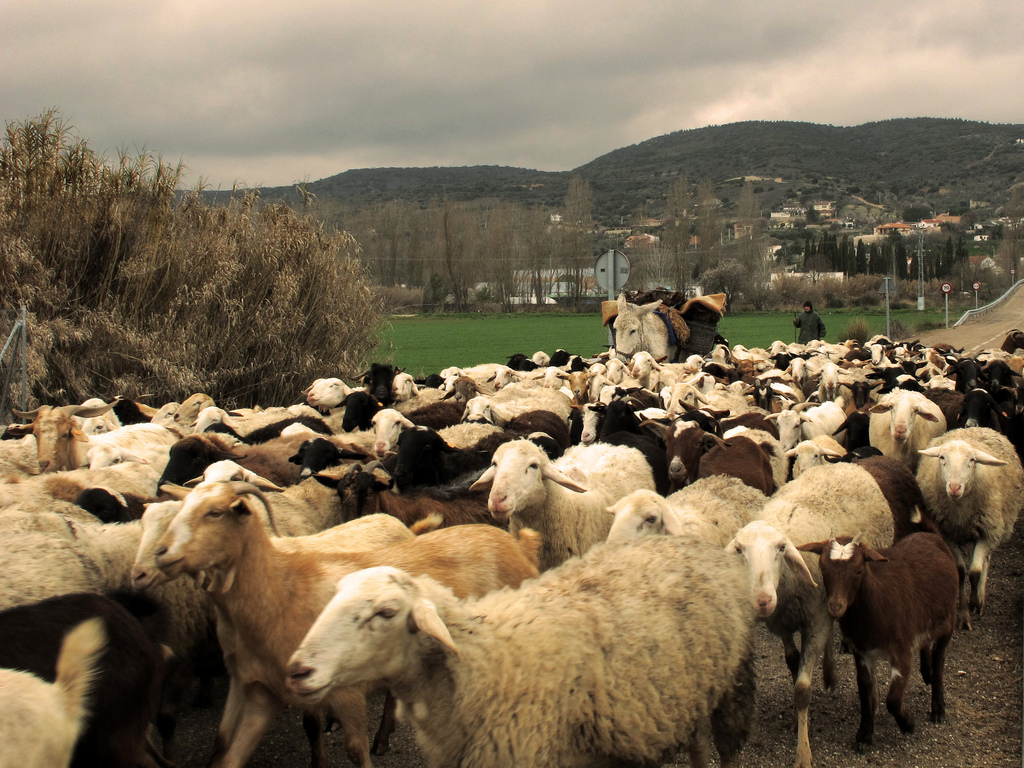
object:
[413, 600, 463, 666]
ear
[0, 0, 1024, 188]
sky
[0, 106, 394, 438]
bush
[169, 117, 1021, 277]
mountains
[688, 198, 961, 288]
buildings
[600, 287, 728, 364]
horse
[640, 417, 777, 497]
sheep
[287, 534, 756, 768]
sheep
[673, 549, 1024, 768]
road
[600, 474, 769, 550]
sheep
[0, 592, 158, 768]
sheep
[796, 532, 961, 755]
sheep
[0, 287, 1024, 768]
livestock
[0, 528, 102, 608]
sheep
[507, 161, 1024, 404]
town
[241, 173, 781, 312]
trees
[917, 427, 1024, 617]
sheep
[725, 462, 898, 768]
sheep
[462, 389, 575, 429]
sheep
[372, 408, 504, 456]
sheep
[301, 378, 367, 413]
sheep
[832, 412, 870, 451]
sheep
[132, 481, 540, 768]
sheep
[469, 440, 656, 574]
sheep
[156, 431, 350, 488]
sheep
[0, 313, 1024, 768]
field